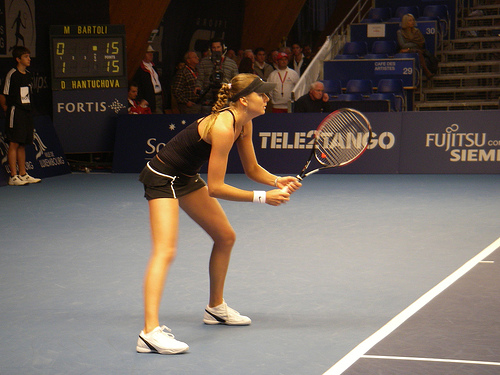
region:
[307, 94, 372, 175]
Black red and white head of a tennis racket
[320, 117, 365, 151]
White netting of a tennis racket with a black logo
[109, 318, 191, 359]
White athletic shoe with a black stripe near the back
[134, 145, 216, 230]
Woman wearing black shorts with a white stripe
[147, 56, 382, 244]
Woman crouching slightly while playing tennis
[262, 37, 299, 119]
Man wearing a white sweater with a red lanyard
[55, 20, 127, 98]
Black score board with yellow writing on it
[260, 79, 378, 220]
a black and red tennis racket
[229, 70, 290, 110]
a black visor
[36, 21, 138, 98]
an electronic scoreboard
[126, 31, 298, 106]
a crowd of standing spectators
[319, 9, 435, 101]
a row of blue stadium seats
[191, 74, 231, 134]
a braid in a woman's hair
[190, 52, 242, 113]
a camera filming the match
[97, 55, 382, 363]
The woman is holding a tennis racket.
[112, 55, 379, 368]
The woman is wearing a tennis uniform.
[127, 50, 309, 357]
The woman is wearing a visor.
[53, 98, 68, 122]
The letter is white.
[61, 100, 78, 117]
The letter is white.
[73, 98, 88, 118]
The letter is white.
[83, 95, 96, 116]
The letter is white.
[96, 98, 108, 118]
The letter is white.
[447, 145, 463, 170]
The letter is white.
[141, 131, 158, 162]
The letter is white.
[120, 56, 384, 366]
this is a tennis player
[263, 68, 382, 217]
a red tennis racket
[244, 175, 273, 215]
a white wrist band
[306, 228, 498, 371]
white lines on the court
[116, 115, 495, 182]
a blue and white sign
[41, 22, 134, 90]
green and black score chart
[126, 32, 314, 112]
a group of people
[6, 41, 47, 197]
man standing in the back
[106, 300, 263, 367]
a pair of white shoes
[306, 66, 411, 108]
a row of seats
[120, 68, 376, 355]
A tennis player.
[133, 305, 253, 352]
Black and white tennis shoes.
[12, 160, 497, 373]
A blue and white tennis court.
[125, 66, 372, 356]
A woman holding a tennis racket.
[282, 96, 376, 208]
A red and black tennis racket.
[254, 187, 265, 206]
A white wristband.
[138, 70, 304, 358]
A woman with a braided ponytail.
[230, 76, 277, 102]
A black sunvisor.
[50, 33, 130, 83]
A digital scoreboard.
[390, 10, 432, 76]
A woman sitting down.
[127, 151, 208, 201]
black colored shorts on woman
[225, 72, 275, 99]
black visor on the woman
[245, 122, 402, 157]
white letters that say "teletango"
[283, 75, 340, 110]
old man sitting in the stands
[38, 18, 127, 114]
scoreboard that shows 15 to 15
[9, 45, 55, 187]
ball boy in black standing up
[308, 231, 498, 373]
white line on court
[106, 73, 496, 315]
a woman bent over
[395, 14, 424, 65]
a woman sitting down